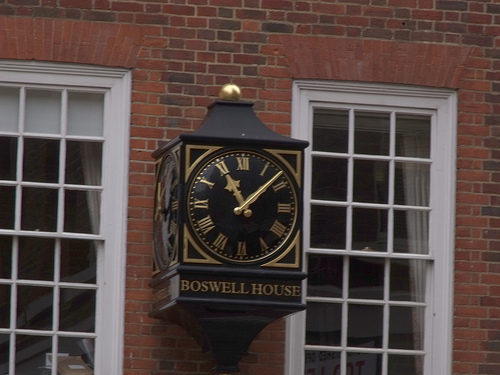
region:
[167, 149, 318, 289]
the clock is black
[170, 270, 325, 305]
text says BOSWELL HOUSE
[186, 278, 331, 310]
the text is gold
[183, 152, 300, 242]
clock's hands are gold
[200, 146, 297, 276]
the clock shows 11:08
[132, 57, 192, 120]
the wall is red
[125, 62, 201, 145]
the wall is bricked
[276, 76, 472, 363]
window pane is white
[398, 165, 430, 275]
the curtain is beige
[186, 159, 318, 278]
the numbers are roman numerals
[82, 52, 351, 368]
a clock outside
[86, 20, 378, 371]
a black and gold clock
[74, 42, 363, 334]
a Boswell House clock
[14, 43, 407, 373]
a clock in between two windows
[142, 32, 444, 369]
a window next to a clock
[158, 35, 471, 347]
a clock next to a window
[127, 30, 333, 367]
a black clock with gold lettering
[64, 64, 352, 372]
a black clock with a gold ball on top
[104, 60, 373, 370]
a black clock with gold arms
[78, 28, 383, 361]
a clock with multiple sides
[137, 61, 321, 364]
black and gold ornate clock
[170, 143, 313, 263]
clock with roman numerals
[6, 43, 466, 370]
two white windows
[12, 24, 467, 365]
brick building with white windows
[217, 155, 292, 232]
gold hands of clock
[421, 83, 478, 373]
white frames of window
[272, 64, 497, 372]
window with small square panes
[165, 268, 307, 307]
Name of building in gold lettering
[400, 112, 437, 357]
white curtains inside windows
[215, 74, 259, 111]
gold decorative ball on top of clock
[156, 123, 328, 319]
The clock says 11:08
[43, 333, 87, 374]
There is a package in the window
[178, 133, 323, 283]
The clock is gold and black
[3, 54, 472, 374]
The clock is between the windows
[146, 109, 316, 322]
The clock is square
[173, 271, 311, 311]
The words say Boswell House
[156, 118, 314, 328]
The words are under the clock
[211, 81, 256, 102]
There is a gold ball at the top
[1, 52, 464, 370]
The windows are white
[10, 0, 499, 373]
The building is brick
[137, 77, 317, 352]
decorative clock on building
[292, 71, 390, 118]
white wood window frame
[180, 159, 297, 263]
clock face on box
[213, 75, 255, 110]
gold ball on clock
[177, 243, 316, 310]
two gold words under clock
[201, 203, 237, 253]
roman numerals on clock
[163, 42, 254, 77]
red bricks on building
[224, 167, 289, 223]
two gold hands on clock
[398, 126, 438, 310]
white curtain on window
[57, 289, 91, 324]
reflection on window pane